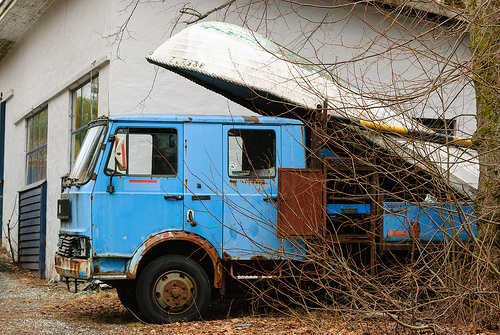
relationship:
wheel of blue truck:
[132, 253, 210, 323] [54, 112, 479, 324]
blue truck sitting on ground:
[54, 112, 479, 324] [19, 275, 450, 333]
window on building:
[22, 99, 48, 186] [0, 2, 482, 292]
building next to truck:
[0, 2, 482, 292] [30, 52, 493, 330]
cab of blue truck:
[53, 115, 313, 322] [54, 112, 479, 324]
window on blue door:
[77, 120, 181, 182] [91, 122, 187, 258]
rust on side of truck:
[168, 229, 235, 279] [16, 85, 421, 289]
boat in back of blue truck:
[145, 19, 475, 196] [54, 112, 479, 324]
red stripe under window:
[128, 179, 157, 183] [107, 126, 179, 178]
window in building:
[22, 99, 48, 186] [0, 2, 482, 292]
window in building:
[70, 67, 100, 170] [0, 2, 482, 292]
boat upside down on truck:
[145, 19, 475, 196] [48, 93, 480, 305]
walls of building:
[51, 0, 105, 54] [0, 2, 482, 292]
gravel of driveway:
[5, 280, 60, 333] [9, 268, 92, 333]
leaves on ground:
[48, 284, 453, 333] [0, 257, 498, 334]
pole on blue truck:
[314, 105, 483, 153] [54, 112, 479, 324]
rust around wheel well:
[275, 157, 343, 246] [115, 226, 223, 286]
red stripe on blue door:
[126, 173, 160, 184] [91, 122, 186, 258]